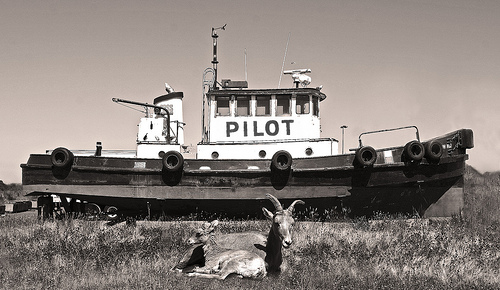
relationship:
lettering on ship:
[223, 119, 293, 136] [21, 23, 476, 225]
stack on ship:
[150, 91, 187, 144] [21, 23, 476, 225]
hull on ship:
[21, 129, 474, 220] [21, 23, 476, 225]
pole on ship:
[208, 30, 222, 88] [21, 23, 476, 225]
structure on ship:
[203, 85, 329, 143] [21, 23, 476, 225]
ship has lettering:
[21, 23, 476, 225] [223, 119, 293, 136]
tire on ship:
[355, 145, 376, 166] [21, 23, 476, 225]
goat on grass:
[170, 188, 306, 274] [3, 215, 498, 288]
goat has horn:
[170, 188, 306, 274] [265, 191, 287, 213]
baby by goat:
[184, 219, 268, 280] [170, 188, 306, 274]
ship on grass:
[21, 23, 476, 225] [3, 215, 498, 288]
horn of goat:
[265, 191, 287, 213] [170, 188, 306, 274]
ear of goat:
[259, 205, 276, 221] [170, 188, 306, 274]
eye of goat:
[274, 219, 280, 227] [170, 188, 306, 274]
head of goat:
[260, 207, 296, 249] [170, 188, 306, 274]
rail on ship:
[355, 125, 422, 148] [21, 23, 476, 225]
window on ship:
[255, 93, 273, 116] [21, 23, 476, 225]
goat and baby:
[170, 188, 306, 274] [184, 219, 268, 280]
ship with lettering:
[21, 23, 476, 225] [223, 119, 293, 136]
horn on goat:
[265, 191, 287, 213] [170, 188, 306, 274]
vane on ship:
[210, 21, 228, 34] [21, 23, 476, 225]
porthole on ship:
[258, 148, 266, 159] [21, 23, 476, 225]